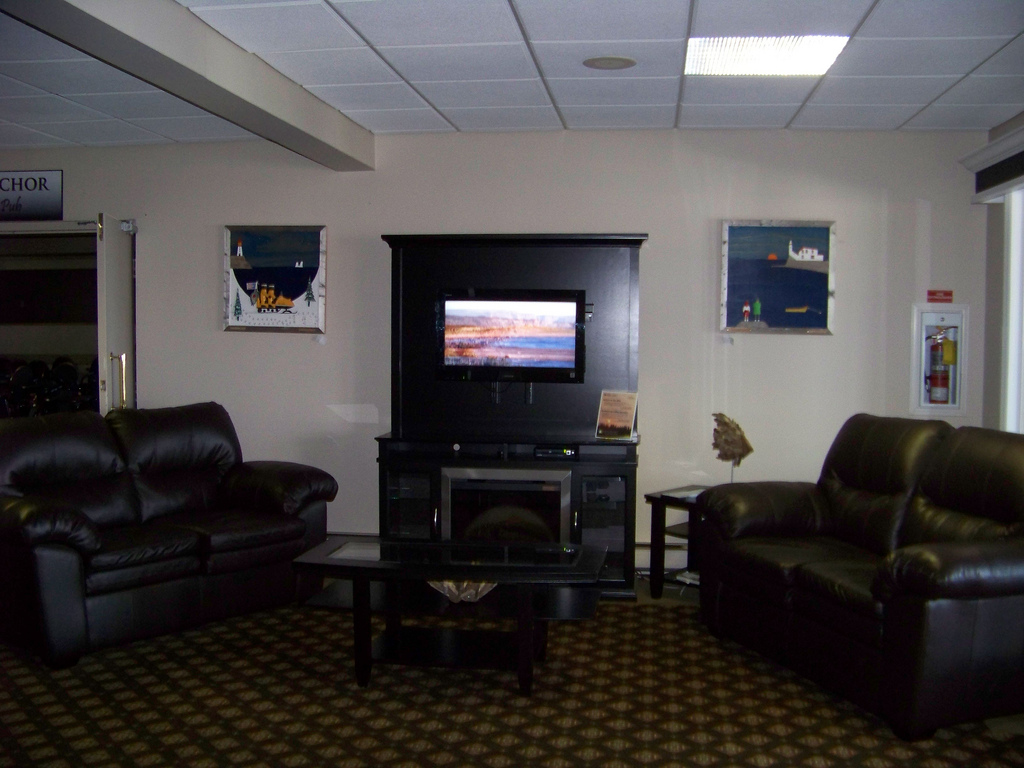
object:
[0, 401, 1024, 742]
couches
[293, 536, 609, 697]
table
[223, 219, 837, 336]
painting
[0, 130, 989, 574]
wall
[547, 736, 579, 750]
design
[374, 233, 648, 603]
furniture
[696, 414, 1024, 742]
couch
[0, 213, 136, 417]
door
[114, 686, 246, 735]
diamond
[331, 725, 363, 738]
design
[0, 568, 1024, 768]
carpet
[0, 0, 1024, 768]
living room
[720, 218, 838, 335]
picture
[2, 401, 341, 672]
couch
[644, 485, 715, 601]
end table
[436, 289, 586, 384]
television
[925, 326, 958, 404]
fire hydrant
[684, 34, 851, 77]
ceiling light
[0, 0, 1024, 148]
ceiling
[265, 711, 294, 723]
pattern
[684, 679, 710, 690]
pattern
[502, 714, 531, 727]
pattern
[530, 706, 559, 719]
pattern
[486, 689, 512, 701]
pattern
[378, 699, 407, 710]
pattern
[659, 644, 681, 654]
pattern